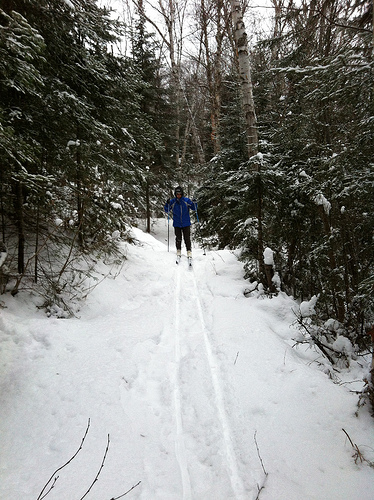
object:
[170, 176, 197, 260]
person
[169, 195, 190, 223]
jacket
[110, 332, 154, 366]
tracks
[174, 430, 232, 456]
snow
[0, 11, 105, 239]
tree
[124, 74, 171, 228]
trees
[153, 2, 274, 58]
sky